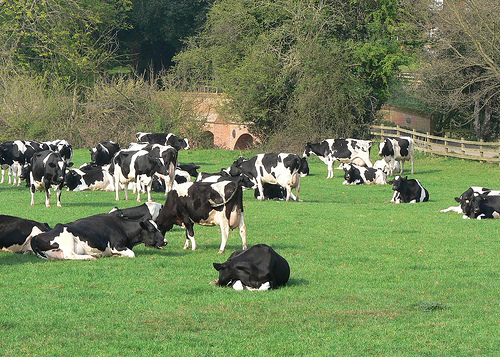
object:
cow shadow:
[131, 248, 186, 255]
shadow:
[196, 242, 306, 249]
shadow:
[278, 275, 310, 287]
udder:
[289, 174, 299, 188]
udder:
[351, 158, 365, 167]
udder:
[155, 163, 176, 181]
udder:
[210, 206, 240, 232]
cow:
[64, 165, 114, 191]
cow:
[440, 186, 500, 220]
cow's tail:
[210, 180, 238, 208]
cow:
[383, 175, 429, 205]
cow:
[302, 138, 375, 179]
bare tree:
[440, 2, 499, 126]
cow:
[208, 243, 293, 294]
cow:
[340, 162, 388, 185]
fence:
[361, 122, 500, 169]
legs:
[181, 211, 198, 251]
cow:
[28, 213, 168, 263]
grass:
[5, 142, 498, 357]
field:
[2, 140, 500, 357]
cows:
[65, 165, 113, 191]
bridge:
[156, 72, 440, 151]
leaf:
[384, 51, 396, 65]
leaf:
[395, 21, 410, 33]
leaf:
[345, 34, 356, 49]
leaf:
[255, 80, 267, 92]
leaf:
[248, 15, 260, 27]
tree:
[2, 1, 133, 91]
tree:
[130, 1, 182, 89]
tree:
[172, 1, 299, 131]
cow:
[28, 149, 73, 207]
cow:
[238, 152, 303, 201]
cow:
[377, 138, 417, 177]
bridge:
[369, 122, 500, 163]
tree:
[224, 1, 395, 152]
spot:
[271, 172, 277, 179]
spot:
[259, 166, 264, 177]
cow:
[138, 180, 249, 255]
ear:
[212, 263, 223, 271]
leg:
[237, 214, 249, 252]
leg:
[217, 215, 231, 255]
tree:
[264, 13, 377, 158]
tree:
[68, 61, 205, 156]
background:
[3, 3, 500, 165]